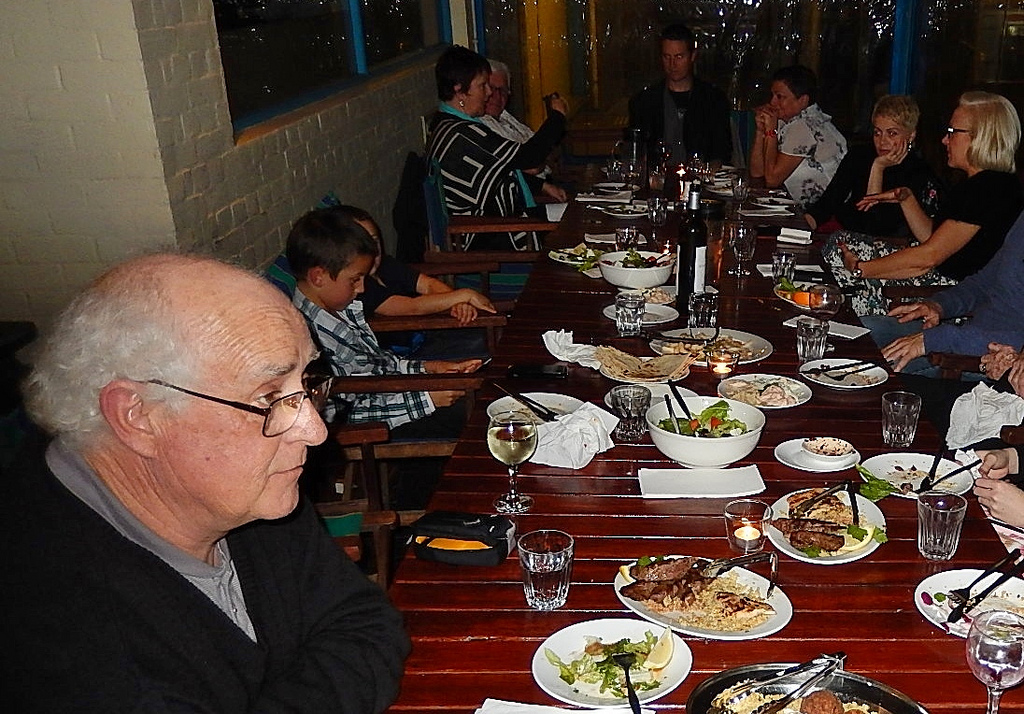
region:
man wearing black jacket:
[4, 263, 415, 712]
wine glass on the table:
[483, 408, 540, 513]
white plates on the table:
[495, 112, 1023, 710]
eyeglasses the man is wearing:
[143, 367, 337, 444]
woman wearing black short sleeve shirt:
[869, 90, 999, 296]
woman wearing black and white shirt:
[433, 49, 574, 250]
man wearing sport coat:
[613, 26, 735, 151]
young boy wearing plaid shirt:
[278, 224, 474, 425]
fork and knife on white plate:
[933, 534, 1020, 634]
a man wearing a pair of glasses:
[24, 244, 335, 574]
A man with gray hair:
[25, 243, 329, 528]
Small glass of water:
[505, 519, 582, 615]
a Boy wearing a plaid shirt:
[293, 200, 448, 413]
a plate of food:
[771, 478, 888, 573]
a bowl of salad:
[651, 379, 766, 475]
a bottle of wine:
[670, 178, 716, 311]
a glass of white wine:
[479, 404, 544, 528]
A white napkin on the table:
[629, 458, 772, 503]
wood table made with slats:
[373, 252, 1021, 712]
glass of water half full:
[508, 533, 582, 613]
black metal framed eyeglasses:
[145, 374, 348, 442]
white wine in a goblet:
[490, 398, 533, 519]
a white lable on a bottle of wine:
[672, 175, 712, 318]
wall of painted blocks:
[3, 1, 438, 283]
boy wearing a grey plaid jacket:
[274, 216, 494, 445]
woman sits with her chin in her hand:
[824, 88, 932, 245]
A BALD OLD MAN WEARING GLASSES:
[2, 254, 426, 711]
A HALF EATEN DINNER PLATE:
[530, 603, 695, 711]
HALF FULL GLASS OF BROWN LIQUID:
[513, 519, 584, 622]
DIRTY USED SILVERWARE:
[941, 545, 1019, 621]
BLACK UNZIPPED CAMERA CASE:
[403, 500, 518, 578]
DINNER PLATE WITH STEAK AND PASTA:
[605, 546, 799, 648]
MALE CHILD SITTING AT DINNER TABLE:
[280, 207, 490, 430]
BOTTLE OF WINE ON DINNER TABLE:
[673, 178, 722, 312]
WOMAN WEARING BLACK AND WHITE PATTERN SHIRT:
[422, 45, 582, 271]